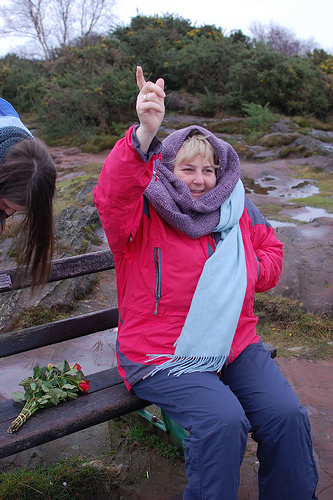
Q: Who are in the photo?
A: People.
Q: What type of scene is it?
A: Outdoor.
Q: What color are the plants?
A: Green.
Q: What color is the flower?
A: Red.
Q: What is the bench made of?
A: Wood.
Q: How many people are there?
A: Two.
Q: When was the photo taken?
A: Daytime.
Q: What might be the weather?
A: Cloudy.